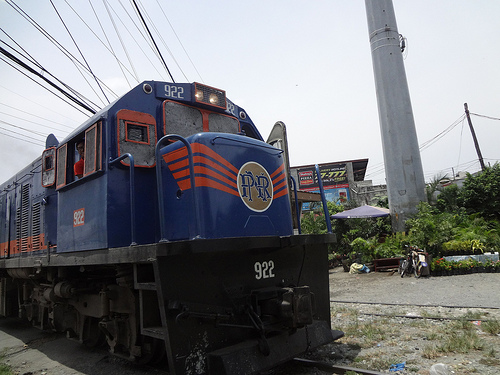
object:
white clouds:
[35, 104, 58, 118]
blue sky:
[0, 0, 500, 187]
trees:
[461, 171, 487, 209]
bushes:
[350, 237, 373, 252]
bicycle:
[398, 244, 429, 278]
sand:
[361, 275, 366, 279]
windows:
[83, 123, 97, 178]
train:
[0, 80, 348, 375]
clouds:
[199, 26, 257, 72]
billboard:
[290, 158, 370, 192]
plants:
[417, 230, 426, 241]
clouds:
[439, 1, 497, 56]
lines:
[162, 142, 239, 174]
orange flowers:
[471, 265, 474, 268]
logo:
[236, 161, 274, 213]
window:
[56, 143, 67, 189]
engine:
[5, 77, 333, 375]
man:
[71, 141, 85, 179]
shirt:
[72, 158, 84, 176]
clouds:
[316, 26, 360, 75]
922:
[253, 260, 276, 280]